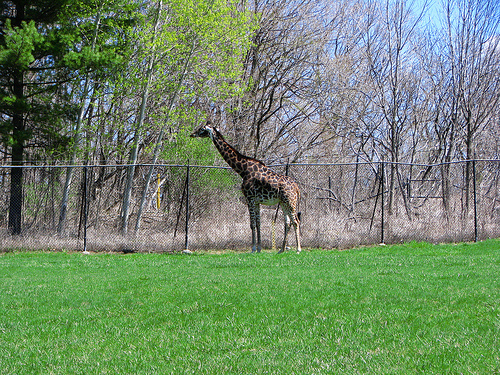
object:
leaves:
[209, 0, 249, 19]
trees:
[365, 0, 425, 224]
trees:
[226, 0, 327, 241]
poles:
[174, 164, 197, 249]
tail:
[295, 186, 303, 222]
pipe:
[156, 173, 161, 210]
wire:
[1, 151, 499, 161]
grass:
[2, 251, 499, 371]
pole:
[0, 158, 500, 168]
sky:
[323, 2, 498, 81]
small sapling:
[56, 0, 258, 253]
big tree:
[0, 0, 153, 236]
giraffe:
[188, 118, 303, 254]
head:
[189, 119, 216, 138]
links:
[108, 235, 158, 245]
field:
[0, 235, 500, 375]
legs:
[289, 209, 301, 253]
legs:
[278, 214, 291, 254]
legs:
[247, 203, 256, 253]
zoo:
[0, 0, 500, 375]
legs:
[254, 199, 262, 252]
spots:
[248, 169, 277, 184]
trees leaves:
[270, 35, 364, 84]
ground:
[182, 259, 497, 372]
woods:
[0, 0, 500, 246]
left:
[0, 0, 193, 265]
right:
[413, 23, 500, 243]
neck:
[214, 136, 249, 177]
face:
[191, 125, 208, 139]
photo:
[0, 0, 500, 375]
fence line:
[0, 236, 500, 254]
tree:
[384, 1, 419, 220]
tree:
[434, 1, 466, 207]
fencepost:
[78, 157, 88, 256]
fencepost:
[379, 154, 384, 243]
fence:
[0, 155, 500, 253]